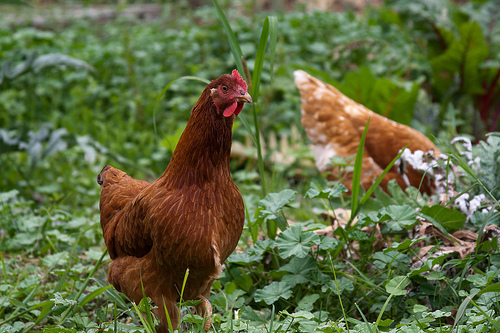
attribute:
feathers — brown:
[181, 164, 226, 222]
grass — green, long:
[1, 8, 484, 331]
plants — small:
[241, 139, 499, 326]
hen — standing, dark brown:
[89, 58, 261, 329]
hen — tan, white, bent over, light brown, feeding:
[282, 62, 467, 243]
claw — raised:
[196, 294, 222, 332]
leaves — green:
[267, 188, 497, 296]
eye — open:
[216, 82, 234, 97]